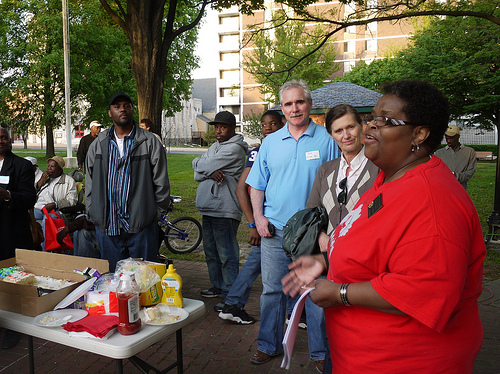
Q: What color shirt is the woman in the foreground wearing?
A: Red.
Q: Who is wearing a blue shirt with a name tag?
A: Man with white hair.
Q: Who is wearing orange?
A: Woman on the right.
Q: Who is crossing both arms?
A: Man in sweatshirt.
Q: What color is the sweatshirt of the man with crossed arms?
A: Gray.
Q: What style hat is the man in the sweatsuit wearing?
A: Fedora.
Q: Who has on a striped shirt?
A: Man closest to table.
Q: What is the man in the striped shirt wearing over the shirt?
A: Jacket.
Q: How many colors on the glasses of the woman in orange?
A: Two.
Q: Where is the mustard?
A: On the table.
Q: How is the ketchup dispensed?
A: Squeeze bottle.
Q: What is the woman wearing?
A: Red shirt.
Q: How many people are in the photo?
A: Twelve.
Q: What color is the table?
A: White.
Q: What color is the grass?
A: Green.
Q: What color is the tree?
A: Green.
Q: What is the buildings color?
A: Red.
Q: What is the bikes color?
A: Blue,black and white.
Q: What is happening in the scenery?
A: Party.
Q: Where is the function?
A: On the street.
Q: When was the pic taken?
A: In the street.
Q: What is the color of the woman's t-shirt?
A: Red.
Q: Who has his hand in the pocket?
A: The man on the left.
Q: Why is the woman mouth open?
A: She is talking.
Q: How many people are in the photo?
A: 11.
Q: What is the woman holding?
A: A book.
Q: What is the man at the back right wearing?
A: A cap.